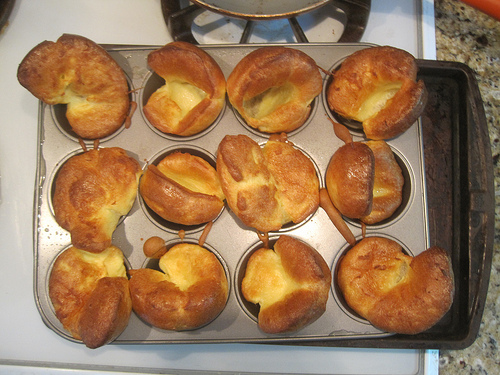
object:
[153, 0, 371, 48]
burner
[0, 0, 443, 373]
oven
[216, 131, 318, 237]
bread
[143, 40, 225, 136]
bread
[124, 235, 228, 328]
bread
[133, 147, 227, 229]
bread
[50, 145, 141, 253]
bread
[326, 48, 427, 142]
bread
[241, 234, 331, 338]
bread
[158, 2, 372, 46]
stove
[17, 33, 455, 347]
baked goods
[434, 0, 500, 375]
counter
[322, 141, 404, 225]
bread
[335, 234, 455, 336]
bread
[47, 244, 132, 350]
bread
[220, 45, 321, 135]
bread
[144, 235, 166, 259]
crumb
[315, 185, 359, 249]
crumb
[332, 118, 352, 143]
crumb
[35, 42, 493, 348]
baking dish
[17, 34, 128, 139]
bread